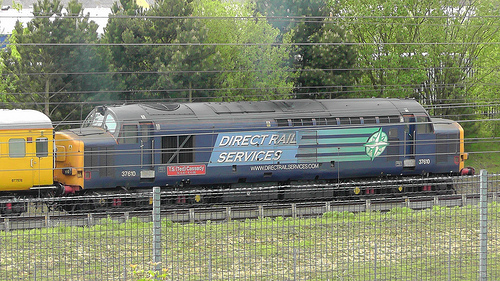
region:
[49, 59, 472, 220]
a train engine going through a forest.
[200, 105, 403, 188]
a painting on a train engine.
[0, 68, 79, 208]
a yellow train car.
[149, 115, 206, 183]
a window on a train.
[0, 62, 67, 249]
a section of a yellow train car.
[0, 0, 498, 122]
a forest of green trees.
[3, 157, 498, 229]
a set of train tracks.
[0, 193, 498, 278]
A field of green grass.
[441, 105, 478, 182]
the end of a train car.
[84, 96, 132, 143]
a window on a train.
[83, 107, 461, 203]
the train is blue and yellow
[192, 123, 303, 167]
the compay is directrail services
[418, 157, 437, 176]
numbers are on the side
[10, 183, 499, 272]
the fence fences the area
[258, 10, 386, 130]
electrical lines are in the air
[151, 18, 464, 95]
trees are in the background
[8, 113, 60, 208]
the train is yellow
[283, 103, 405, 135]
vents are on the train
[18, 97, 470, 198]
the train is a cargo train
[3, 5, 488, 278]
the scene is outdoors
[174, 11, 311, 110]
this is a tree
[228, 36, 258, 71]
the leaves are green in color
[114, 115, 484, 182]
this is a train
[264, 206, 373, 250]
this is the fence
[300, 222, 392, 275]
this is a wire mess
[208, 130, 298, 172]
this is a writing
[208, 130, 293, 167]
the writing is in white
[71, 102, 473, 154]
this is the head of the train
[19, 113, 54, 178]
this is a container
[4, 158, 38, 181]
the container is yellow in color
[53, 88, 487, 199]
a gray engine of a train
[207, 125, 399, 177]
A blue white and green logo on side of engine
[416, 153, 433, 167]
white numbers by front of engine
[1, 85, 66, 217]
a yellow train car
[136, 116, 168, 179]
a door near the rear of the engine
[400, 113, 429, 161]
a door near the front of the engine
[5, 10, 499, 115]
a row of trees behind the train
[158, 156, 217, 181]
a red sign with white writing on train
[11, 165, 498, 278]
a fence along side of train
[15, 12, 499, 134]
wires above the train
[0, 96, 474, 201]
the train on the track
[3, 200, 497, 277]
the green grass near the train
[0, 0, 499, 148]
the trees behind the train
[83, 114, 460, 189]
the words and numbers on the side of the blue train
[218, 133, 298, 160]
the words DIRECT RAIL SERVICES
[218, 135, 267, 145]
the word DIRECT on the train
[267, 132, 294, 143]
the word RAIL on the train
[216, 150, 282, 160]
the word SERVICES on the train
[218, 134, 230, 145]
the letter D on the train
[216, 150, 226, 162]
the letter S on the train